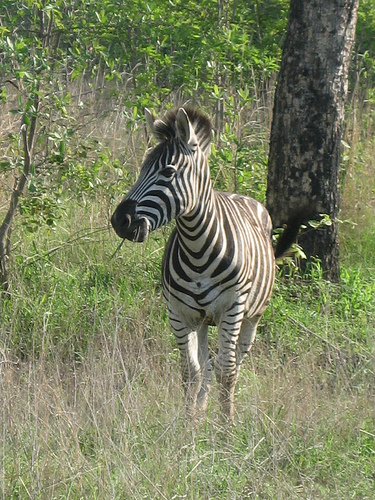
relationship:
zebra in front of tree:
[111, 104, 277, 419] [265, 0, 360, 279]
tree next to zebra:
[0, 34, 64, 273] [111, 104, 277, 419]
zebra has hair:
[111, 104, 277, 419] [152, 106, 212, 146]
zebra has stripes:
[111, 104, 277, 419] [214, 189, 276, 312]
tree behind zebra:
[265, 0, 360, 279] [111, 104, 277, 419]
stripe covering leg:
[165, 314, 183, 325] [161, 307, 206, 410]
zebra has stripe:
[111, 104, 277, 419] [174, 338, 194, 347]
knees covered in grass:
[178, 364, 240, 383] [1, 257, 374, 500]